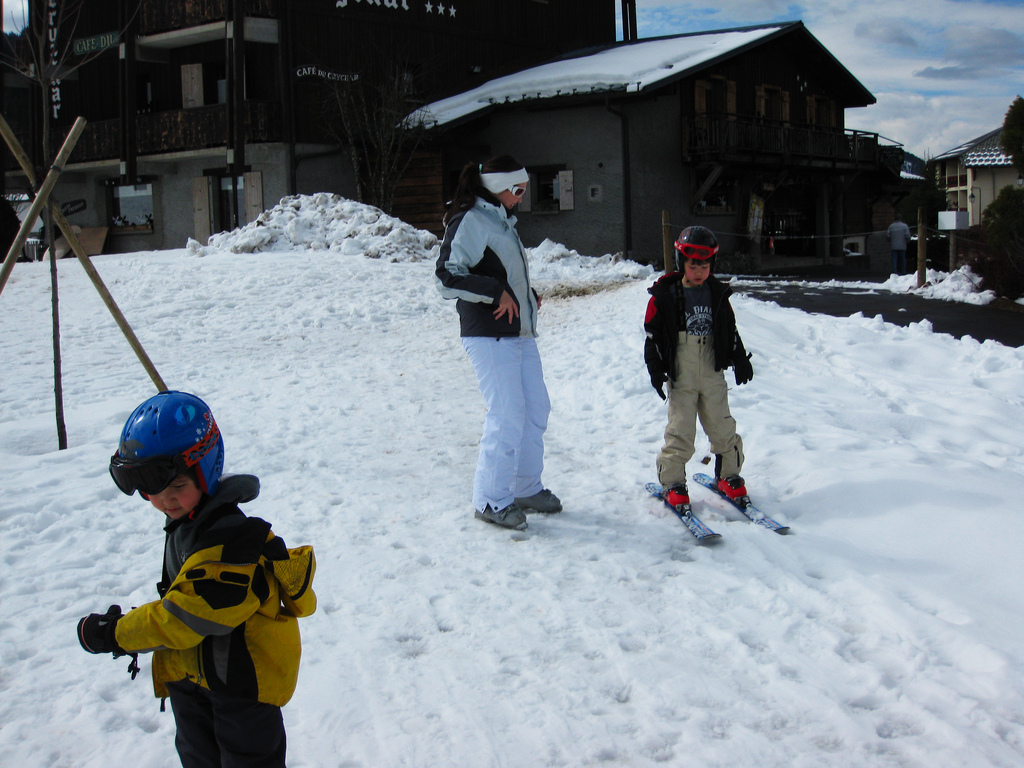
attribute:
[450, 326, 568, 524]
pants — white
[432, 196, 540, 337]
coat — black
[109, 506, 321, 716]
coat — black, yellow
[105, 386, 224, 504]
helmet — blue 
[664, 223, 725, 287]
helmet — black 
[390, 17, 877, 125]
roof — black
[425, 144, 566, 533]
woman — gray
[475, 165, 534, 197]
headband — white 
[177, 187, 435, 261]
pile — dirty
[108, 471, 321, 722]
jacket — yellow, black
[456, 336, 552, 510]
pants — white 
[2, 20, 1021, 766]
snow — white 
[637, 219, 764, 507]
child — skiing , standing 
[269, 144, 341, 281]
snow — dirty